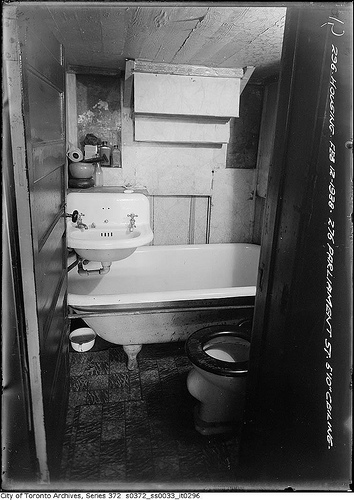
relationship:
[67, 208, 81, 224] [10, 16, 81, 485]
handle on door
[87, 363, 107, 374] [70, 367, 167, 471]
tile on floor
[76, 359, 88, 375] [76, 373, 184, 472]
tile on floor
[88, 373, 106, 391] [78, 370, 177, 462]
tile on floor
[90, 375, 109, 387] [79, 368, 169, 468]
tile on floor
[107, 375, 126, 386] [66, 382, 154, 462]
tile on floor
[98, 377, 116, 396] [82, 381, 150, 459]
tile on floor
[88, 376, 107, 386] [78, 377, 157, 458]
tile on floor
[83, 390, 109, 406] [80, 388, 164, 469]
tile on floor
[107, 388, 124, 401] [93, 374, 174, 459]
tile on floor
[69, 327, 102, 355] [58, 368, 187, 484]
bowl on floor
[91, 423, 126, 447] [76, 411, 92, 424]
tile on floor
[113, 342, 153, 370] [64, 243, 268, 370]
leg on white tub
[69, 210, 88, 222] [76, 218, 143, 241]
tap in sink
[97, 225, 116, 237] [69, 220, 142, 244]
slits in sink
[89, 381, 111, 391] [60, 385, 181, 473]
tile on floor